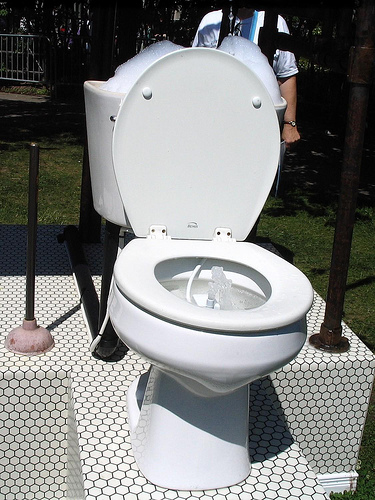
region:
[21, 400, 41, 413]
tiny cell tile of a restroom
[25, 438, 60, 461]
tiny cell tile of a restroom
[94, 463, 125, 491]
tiny cell tile of a restroom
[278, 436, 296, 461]
tiny cell tile of a restroom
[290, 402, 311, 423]
tiny cell tile of a restroom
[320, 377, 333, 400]
tiny cell tile of a restroom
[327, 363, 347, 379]
tiny cell tile of a restroom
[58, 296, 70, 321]
tiny cell tile of a restroom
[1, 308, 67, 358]
sponger of a toilet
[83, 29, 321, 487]
white toilet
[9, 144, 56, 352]
plunger with black handle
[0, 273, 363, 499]
white and black flooring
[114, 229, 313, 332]
white seat on the toilet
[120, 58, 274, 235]
white lid of the toilet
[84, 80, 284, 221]
white tank of the toilet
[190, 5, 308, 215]
person walking behind the toilet display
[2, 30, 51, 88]
silver railing beside the sidewalk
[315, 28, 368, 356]
black pole next to toilet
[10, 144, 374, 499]
grass the toilet display is on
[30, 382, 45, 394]
tiny cell tiles of a restroom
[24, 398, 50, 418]
tiny cell tiles of a restroom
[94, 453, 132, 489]
tiny cell tiles of a restroom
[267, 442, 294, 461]
tiny cell tiles of a restroom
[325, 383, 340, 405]
tiny cell tiles of a restroom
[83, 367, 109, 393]
tiny cell tiles of a restroom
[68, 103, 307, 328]
a white toilet outside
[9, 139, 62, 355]
a plunger in the scene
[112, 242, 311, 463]
the toilet is clean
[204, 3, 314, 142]
a guy standing in the area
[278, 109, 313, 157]
a watch on the man's hand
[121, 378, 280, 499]
the base of the toilet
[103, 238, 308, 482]
the toilet is white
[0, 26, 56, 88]
a gate in the background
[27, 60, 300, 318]
this toilet is in an open area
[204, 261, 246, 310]
Water flowing from within a toilet.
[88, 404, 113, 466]
A hexagonal pattern on the floor.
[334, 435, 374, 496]
Small weeds growing near the floor.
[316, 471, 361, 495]
A white baseboard with three lines across it.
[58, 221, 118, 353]
A back pipe extends from the back of the toilet.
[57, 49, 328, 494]
A large outdoor toilet.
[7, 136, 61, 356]
A long toilet plunger with black handle.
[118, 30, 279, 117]
Soap bubbling up from the toilet tank.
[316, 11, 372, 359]
A black metal pipe coming up from the floor.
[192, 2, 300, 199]
A person standing behind the toilet.